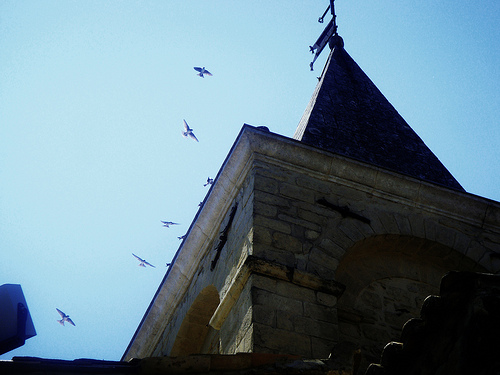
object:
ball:
[328, 34, 342, 49]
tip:
[328, 33, 349, 57]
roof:
[1, 349, 499, 373]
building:
[118, 0, 499, 371]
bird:
[194, 67, 212, 78]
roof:
[296, 48, 464, 228]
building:
[307, 103, 447, 303]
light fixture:
[0, 282, 38, 355]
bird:
[177, 234, 189, 241]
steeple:
[290, 45, 470, 192]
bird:
[132, 253, 155, 267]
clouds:
[392, 15, 459, 94]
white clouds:
[37, 22, 111, 100]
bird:
[54, 308, 75, 328]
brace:
[317, 200, 372, 225]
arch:
[308, 212, 494, 357]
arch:
[169, 284, 226, 367]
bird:
[198, 201, 205, 209]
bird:
[183, 119, 200, 142]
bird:
[159, 219, 180, 227]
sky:
[0, 0, 499, 362]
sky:
[83, 38, 124, 67]